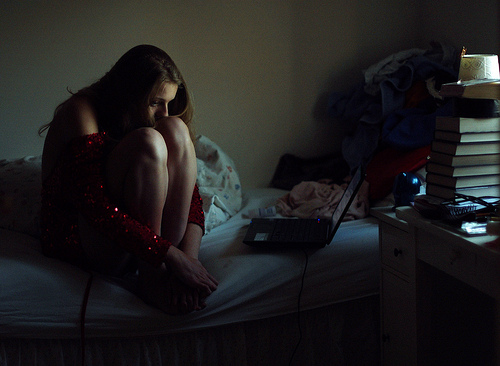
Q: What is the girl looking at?
A: Laptop.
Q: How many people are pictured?
A: One.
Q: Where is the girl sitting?
A: Bed.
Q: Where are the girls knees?
A: Pulled up in front of her.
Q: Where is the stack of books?
A: To the right.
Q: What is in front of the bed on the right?
A: A desk.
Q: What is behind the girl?
A: Bedspread.